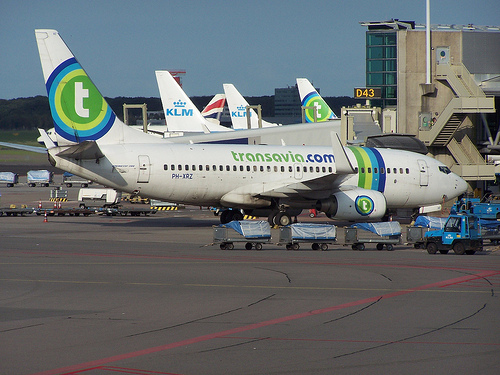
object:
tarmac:
[1, 208, 500, 374]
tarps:
[211, 198, 500, 255]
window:
[163, 163, 210, 172]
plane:
[30, 28, 468, 254]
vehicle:
[424, 214, 500, 256]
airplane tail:
[31, 29, 136, 146]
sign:
[356, 88, 375, 98]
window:
[212, 162, 217, 174]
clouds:
[84, 26, 177, 93]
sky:
[0, 0, 499, 102]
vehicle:
[423, 204, 497, 254]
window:
[163, 163, 410, 175]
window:
[309, 165, 315, 174]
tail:
[34, 28, 123, 138]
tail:
[155, 69, 209, 131]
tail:
[222, 82, 278, 129]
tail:
[296, 78, 338, 124]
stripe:
[200, 93, 226, 121]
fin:
[201, 92, 225, 125]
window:
[163, 164, 167, 170]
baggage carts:
[211, 215, 459, 253]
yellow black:
[50, 197, 68, 202]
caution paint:
[48, 189, 68, 202]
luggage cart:
[343, 221, 402, 250]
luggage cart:
[279, 223, 337, 251]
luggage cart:
[213, 220, 272, 250]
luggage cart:
[406, 214, 448, 249]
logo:
[173, 99, 186, 107]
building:
[354, 18, 499, 200]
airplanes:
[31, 27, 468, 224]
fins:
[32, 29, 337, 134]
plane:
[35, 28, 469, 233]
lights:
[354, 88, 382, 99]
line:
[32, 29, 471, 229]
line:
[215, 218, 452, 248]